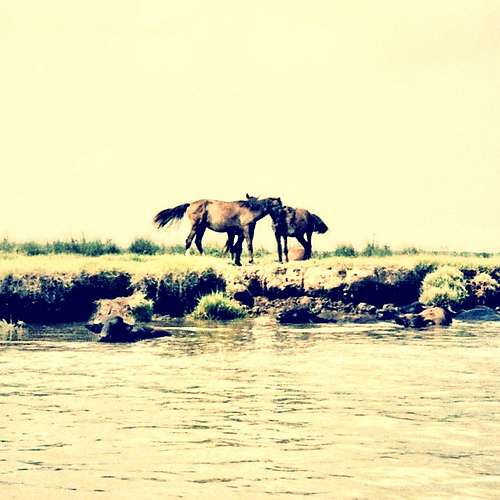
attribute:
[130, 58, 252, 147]
clouds — white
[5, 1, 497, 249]
sky — white, cloudy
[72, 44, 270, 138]
skies — cloudy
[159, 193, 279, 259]
horse — playing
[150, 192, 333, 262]
horses — playing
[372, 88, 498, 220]
sky — cloudy, white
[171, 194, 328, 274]
horse — brown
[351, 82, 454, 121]
sky — cloudy, white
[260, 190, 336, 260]
horse — brown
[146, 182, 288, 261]
horse — brown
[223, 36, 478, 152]
clouds — white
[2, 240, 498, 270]
grass — green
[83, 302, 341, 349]
cows — black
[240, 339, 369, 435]
water — flowing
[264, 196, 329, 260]
horse — playing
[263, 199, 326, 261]
horse — brown